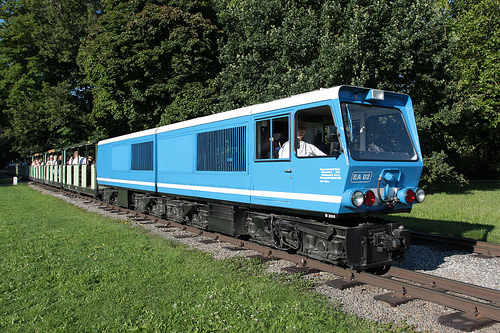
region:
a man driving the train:
[263, 110, 350, 173]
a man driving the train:
[259, 94, 340, 211]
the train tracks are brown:
[161, 197, 367, 331]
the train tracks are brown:
[289, 243, 440, 330]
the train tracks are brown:
[77, 181, 257, 293]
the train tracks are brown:
[344, 258, 461, 329]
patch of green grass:
[172, 289, 181, 303]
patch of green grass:
[113, 268, 134, 284]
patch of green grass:
[89, 295, 111, 317]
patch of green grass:
[86, 229, 112, 256]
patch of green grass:
[436, 212, 462, 229]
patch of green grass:
[73, 231, 98, 253]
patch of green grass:
[69, 292, 92, 316]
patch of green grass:
[66, 223, 87, 240]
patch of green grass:
[26, 288, 54, 310]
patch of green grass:
[74, 234, 86, 250]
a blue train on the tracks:
[16, 98, 423, 266]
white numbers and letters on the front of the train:
[349, 170, 371, 185]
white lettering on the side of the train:
[315, 167, 345, 185]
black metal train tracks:
[401, 267, 485, 322]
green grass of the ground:
[56, 234, 159, 302]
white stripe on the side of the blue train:
[188, 184, 288, 203]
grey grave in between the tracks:
[440, 247, 490, 284]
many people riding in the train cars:
[23, 149, 91, 174]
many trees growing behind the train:
[1, 3, 476, 112]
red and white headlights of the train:
[342, 179, 430, 222]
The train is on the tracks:
[15, 31, 455, 328]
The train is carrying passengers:
[5, 45, 475, 310]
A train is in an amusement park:
[10, 40, 470, 320]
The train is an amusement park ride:
[10, 35, 465, 310]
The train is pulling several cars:
[6, 45, 471, 293]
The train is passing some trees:
[7, 32, 483, 308]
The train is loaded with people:
[5, 48, 480, 311]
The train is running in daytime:
[17, 37, 485, 308]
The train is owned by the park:
[1, 35, 476, 300]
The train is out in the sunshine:
[6, 38, 475, 312]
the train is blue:
[66, 82, 416, 232]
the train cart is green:
[19, 143, 136, 213]